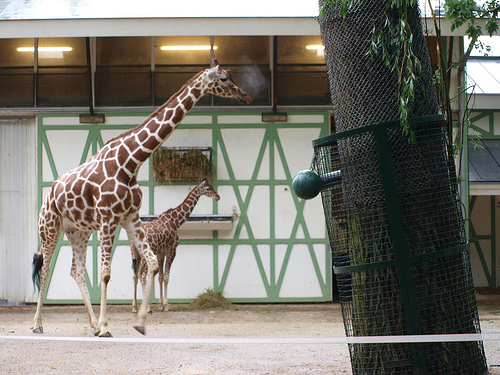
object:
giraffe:
[32, 59, 250, 339]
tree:
[309, 2, 482, 374]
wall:
[35, 115, 346, 300]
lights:
[16, 43, 327, 52]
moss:
[332, 0, 436, 138]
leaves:
[316, 1, 500, 140]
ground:
[3, 300, 500, 374]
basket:
[153, 143, 213, 187]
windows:
[3, 38, 338, 110]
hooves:
[29, 320, 148, 336]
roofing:
[461, 133, 499, 191]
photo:
[0, 3, 499, 371]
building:
[1, 2, 497, 325]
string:
[3, 331, 500, 349]